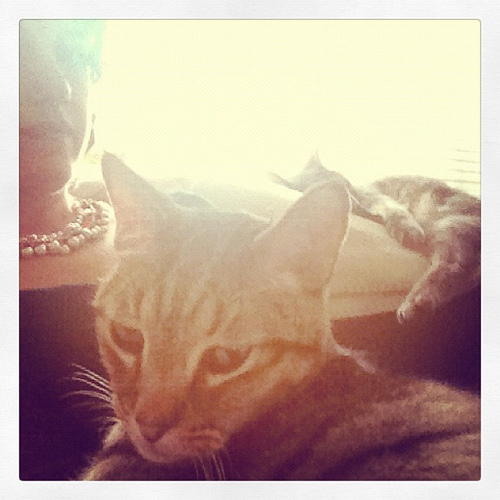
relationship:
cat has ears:
[55, 148, 480, 479] [85, 142, 365, 306]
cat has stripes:
[69, 258, 352, 459] [148, 280, 184, 333]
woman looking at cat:
[22, 25, 96, 301] [77, 140, 462, 461]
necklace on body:
[20, 190, 113, 260] [25, 26, 125, 439]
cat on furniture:
[295, 150, 472, 270] [312, 260, 474, 380]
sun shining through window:
[131, 37, 410, 167] [91, 23, 478, 188]